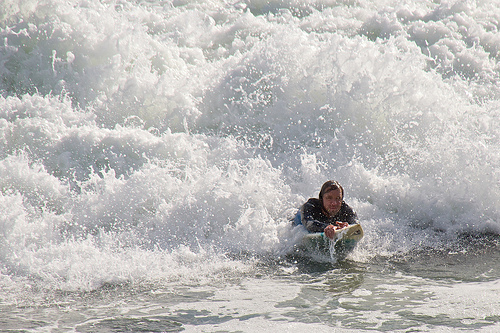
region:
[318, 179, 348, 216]
the head of a man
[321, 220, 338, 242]
the hand of a man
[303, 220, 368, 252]
a white surf board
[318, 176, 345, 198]
the hair of a man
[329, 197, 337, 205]
the nose of a man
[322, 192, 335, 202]
the eye of a man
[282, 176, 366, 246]
a man on the surfboard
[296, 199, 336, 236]
the arm of a man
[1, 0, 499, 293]
a crashing white wave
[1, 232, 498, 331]
a calm area of water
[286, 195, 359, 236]
a black wet suit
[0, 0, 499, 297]
a white foaming wave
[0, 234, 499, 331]
calm water in front of the man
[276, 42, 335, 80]
part of some water splashes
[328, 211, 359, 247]
edge of a swimming board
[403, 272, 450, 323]
part of some water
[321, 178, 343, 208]
face of a man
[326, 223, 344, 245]
hand of a man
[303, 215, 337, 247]
part of a man's arm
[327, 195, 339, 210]
nose of a man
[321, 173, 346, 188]
hair of a man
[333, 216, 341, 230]
part of a thumb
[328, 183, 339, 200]
head of the man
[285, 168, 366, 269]
man lying on surfboard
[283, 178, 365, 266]
man gripping surfboard with two hands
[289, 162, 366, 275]
man with brown hair surfing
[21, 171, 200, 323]
choppy ocean waves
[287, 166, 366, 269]
man with wetsuit surfing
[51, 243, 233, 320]
choppy waves breaking on sand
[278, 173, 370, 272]
white male surfing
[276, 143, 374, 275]
white male surfing in choppy water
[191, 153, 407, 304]
surfer in violent waves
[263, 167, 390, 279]
man on yellow and blue surfboard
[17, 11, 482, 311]
Picture is taken outside.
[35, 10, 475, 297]
Picture is taken during the day time.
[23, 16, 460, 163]
The sun is out in the picture.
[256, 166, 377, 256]
A person is on a surfboard.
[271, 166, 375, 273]
The person is laying on top of the surf board.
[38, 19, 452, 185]
A large wave is crashing behind the surfer.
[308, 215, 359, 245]
The surfer is holding on to the top of the surfboard.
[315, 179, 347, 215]
The surfer's hair is blonde.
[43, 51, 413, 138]
The waves are white in color.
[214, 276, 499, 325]
White suds are on the water.